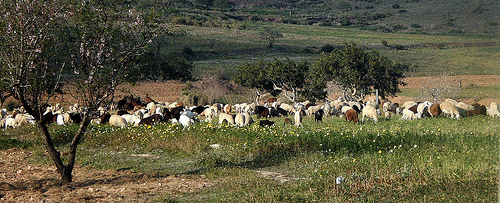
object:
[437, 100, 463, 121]
sheep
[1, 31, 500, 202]
field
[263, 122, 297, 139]
flowers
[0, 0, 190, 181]
tree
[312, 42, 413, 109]
trees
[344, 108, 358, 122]
sheep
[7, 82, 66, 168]
branches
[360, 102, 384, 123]
sheep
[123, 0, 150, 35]
flowers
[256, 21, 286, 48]
tree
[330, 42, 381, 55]
tops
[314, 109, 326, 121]
sheep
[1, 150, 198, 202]
dirt